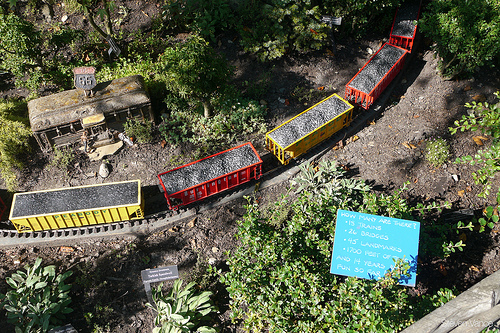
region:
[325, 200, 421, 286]
Blue sign with white writing.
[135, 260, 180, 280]
Black sign with white writing.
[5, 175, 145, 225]
Yellow train car with writing.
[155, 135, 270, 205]
Red train car with writing.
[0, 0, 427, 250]
Train tracks with a train on it.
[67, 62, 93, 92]
Old rusty sign with numbers on it.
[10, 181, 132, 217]
Coal in a yellow train car.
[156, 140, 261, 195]
Coal in a red train car.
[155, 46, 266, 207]
Green tree next to train tracks.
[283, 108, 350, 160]
Green writing on a train car.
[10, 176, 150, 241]
yellow train car with coal in it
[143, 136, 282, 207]
red train car with coal in it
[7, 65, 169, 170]
a little train station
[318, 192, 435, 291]
A blue sign with words and numbers on it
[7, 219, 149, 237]
Part of a train track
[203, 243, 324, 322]
Many green leaves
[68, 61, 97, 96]
Little route 66 sign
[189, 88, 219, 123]
A fat brown tree trunk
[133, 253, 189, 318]
A sign with words on it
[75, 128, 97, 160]
A very small person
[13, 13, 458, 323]
a mini train display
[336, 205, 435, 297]
a text card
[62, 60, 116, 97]
route 66 sign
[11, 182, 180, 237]
yellow mini train full of gravel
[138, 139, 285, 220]
a mini red train full of gravel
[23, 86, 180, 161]
dirty mini train station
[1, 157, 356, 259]
mini train track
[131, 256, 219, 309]
miniature wood sign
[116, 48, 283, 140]
green ground cover plant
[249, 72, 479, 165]
sunlight on a miniature train set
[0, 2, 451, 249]
a model railroad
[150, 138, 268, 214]
a red model railroad coal car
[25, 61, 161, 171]
a route 66 model diner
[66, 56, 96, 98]
a route 66 sign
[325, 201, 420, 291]
a blue informational sign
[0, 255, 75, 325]
a green plant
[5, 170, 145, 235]
a yellow model railroad coal car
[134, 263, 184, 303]
an informational sign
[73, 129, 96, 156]
a model railroad figurine of a person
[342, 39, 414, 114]
a red model railroad coal car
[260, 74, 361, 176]
yellow train car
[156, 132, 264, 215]
red train car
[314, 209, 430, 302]
large blue sign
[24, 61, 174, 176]
small wooden structure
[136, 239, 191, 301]
small structure made of wood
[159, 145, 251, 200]
coal inside of red train car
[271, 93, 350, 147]
coal inside of yellow train car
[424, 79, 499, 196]
patch of green brush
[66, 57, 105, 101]
road sign on building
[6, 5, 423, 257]
train tracks on hillside